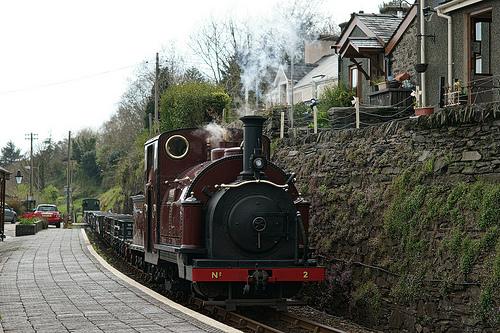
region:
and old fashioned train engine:
[122, 114, 330, 302]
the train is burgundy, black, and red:
[137, 122, 300, 295]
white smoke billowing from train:
[223, 19, 300, 113]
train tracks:
[203, 291, 364, 331]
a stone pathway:
[20, 234, 151, 331]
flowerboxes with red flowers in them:
[12, 210, 49, 237]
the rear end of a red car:
[33, 201, 69, 234]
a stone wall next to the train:
[272, 126, 495, 309]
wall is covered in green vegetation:
[350, 172, 495, 294]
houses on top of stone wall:
[235, 11, 498, 112]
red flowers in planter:
[16, 210, 45, 235]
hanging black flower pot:
[412, 28, 432, 79]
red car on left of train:
[38, 202, 60, 224]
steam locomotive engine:
[107, 107, 315, 304]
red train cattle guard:
[200, 262, 332, 289]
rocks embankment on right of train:
[310, 100, 497, 260]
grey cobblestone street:
[0, 227, 166, 331]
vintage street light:
[11, 170, 28, 228]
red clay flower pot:
[412, 97, 431, 123]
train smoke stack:
[232, 107, 269, 178]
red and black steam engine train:
[77, 109, 329, 294]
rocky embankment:
[266, 98, 498, 331]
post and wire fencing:
[276, 87, 420, 141]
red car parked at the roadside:
[34, 201, 65, 228]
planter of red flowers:
[14, 210, 47, 235]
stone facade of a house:
[385, 1, 422, 86]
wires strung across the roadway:
[2, 50, 237, 94]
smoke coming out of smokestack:
[203, 66, 271, 180]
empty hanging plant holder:
[411, 29, 437, 74]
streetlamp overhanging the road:
[13, 163, 40, 210]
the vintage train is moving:
[101, 51, 398, 313]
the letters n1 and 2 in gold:
[181, 234, 352, 288]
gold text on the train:
[120, 224, 365, 325]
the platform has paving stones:
[14, 170, 226, 328]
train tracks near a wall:
[156, 203, 352, 331]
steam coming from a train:
[128, 61, 380, 223]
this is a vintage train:
[94, 75, 399, 328]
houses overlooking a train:
[136, 29, 486, 231]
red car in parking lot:
[16, 170, 143, 287]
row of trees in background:
[132, 57, 342, 211]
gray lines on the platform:
[38, 270, 128, 330]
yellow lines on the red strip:
[205, 261, 233, 294]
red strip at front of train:
[189, 256, 381, 303]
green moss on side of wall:
[371, 176, 465, 250]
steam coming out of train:
[220, 52, 277, 154]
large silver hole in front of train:
[151, 123, 196, 168]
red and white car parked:
[17, 189, 72, 226]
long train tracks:
[177, 280, 343, 330]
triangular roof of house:
[315, 5, 388, 62]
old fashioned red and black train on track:
[86, 90, 321, 310]